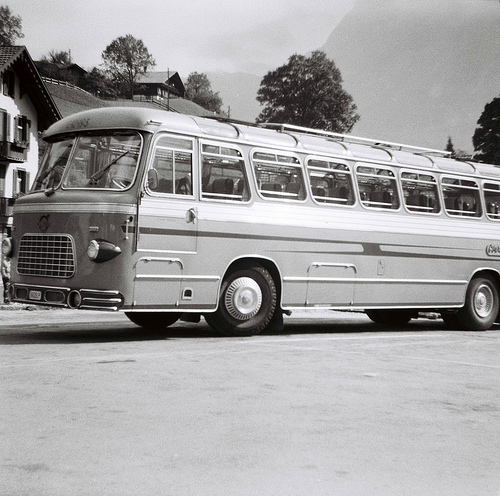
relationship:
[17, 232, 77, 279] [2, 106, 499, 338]
grill on bus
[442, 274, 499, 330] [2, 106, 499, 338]
wheel on bus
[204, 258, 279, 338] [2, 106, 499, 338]
wheel on bus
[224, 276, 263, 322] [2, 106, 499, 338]
hub on bus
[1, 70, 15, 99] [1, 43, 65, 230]
window on house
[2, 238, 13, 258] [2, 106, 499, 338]
headlight on bus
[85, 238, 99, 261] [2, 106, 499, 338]
headlight on bus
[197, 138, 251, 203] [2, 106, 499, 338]
window on bus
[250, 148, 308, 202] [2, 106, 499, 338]
window on bus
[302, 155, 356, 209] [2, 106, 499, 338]
window on bus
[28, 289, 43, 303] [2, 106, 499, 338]
plate on bus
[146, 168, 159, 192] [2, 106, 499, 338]
mirror on bus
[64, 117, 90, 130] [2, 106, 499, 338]
number on bus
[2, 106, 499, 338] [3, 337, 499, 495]
bus on road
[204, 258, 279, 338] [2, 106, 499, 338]
tire of bus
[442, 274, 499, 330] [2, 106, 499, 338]
tire of bus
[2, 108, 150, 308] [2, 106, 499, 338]
front of bus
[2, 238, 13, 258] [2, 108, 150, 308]
headlight on front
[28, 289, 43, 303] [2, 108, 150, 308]
plate on front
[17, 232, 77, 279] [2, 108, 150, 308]
grill on front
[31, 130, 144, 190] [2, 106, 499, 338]
windshield on bus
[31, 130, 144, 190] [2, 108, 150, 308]
windshield on front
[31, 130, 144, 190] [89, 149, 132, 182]
windshield with wiper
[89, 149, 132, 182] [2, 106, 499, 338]
wiper on bus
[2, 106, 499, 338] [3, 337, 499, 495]
bus on street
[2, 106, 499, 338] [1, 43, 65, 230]
bus by house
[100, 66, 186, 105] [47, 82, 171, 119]
house on hill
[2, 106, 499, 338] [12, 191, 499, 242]
bus has stripe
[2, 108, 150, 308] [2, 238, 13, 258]
front bus headlight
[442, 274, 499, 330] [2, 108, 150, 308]
wheel on front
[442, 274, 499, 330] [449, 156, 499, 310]
wheel on rear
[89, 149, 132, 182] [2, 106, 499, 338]
wiper on vehicle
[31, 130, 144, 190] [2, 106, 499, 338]
windshield on vehicle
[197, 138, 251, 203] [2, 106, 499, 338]
window on vehicle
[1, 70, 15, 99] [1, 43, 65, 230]
window on building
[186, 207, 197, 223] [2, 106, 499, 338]
handle on vehicle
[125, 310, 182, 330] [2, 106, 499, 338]
tire on bus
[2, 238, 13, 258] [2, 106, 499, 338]
headlight of bus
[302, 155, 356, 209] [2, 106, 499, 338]
window on side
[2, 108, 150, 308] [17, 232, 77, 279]
front of grill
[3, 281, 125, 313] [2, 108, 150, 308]
bumper on front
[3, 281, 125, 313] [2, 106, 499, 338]
bumper on bus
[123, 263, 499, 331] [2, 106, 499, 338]
wheels of bus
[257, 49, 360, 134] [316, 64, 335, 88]
tree with leaves